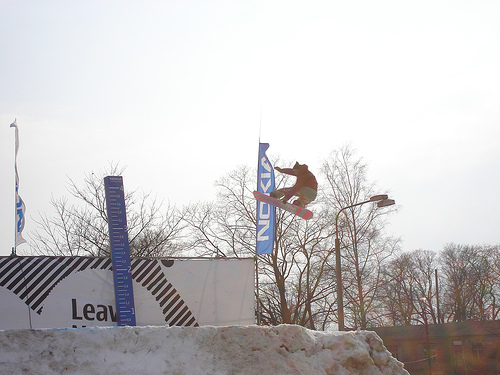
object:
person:
[270, 161, 317, 208]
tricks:
[253, 161, 318, 220]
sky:
[42, 18, 91, 31]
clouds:
[0, 0, 500, 117]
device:
[103, 176, 137, 327]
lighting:
[335, 194, 396, 332]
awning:
[366, 319, 500, 340]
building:
[360, 321, 500, 375]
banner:
[256, 143, 276, 255]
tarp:
[0, 256, 68, 328]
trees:
[24, 148, 500, 332]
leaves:
[450, 248, 481, 259]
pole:
[355, 261, 372, 293]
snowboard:
[252, 190, 313, 220]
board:
[0, 256, 255, 331]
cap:
[298, 164, 308, 175]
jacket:
[282, 164, 317, 200]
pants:
[270, 185, 317, 208]